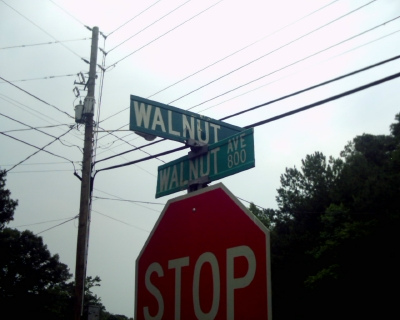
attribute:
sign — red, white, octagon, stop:
[134, 181, 274, 319]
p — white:
[225, 244, 254, 318]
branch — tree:
[329, 157, 344, 167]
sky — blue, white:
[3, 0, 399, 316]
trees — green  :
[248, 112, 398, 317]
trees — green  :
[1, 168, 123, 318]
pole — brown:
[71, 24, 99, 319]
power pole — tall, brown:
[56, 167, 126, 297]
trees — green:
[1, 185, 120, 318]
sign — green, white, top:
[128, 94, 244, 148]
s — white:
[135, 248, 185, 314]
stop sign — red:
[124, 176, 292, 316]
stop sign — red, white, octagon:
[132, 181, 278, 318]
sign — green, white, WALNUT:
[123, 90, 240, 149]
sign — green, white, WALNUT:
[151, 129, 260, 198]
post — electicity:
[75, 22, 98, 318]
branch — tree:
[40, 252, 73, 289]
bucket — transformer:
[73, 102, 85, 124]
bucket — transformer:
[79, 93, 96, 117]